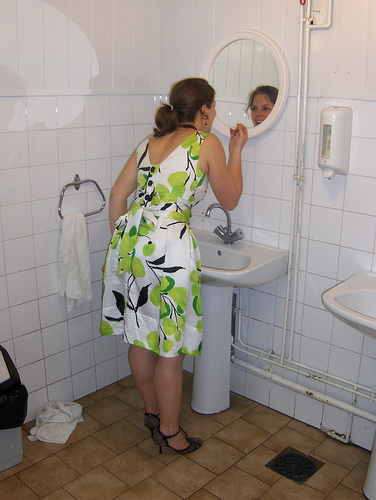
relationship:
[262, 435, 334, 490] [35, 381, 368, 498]
drain in floor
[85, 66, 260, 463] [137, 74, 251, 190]
lady fixing make up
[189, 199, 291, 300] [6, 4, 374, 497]
sink of bathroom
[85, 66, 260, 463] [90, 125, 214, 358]
lady has party dress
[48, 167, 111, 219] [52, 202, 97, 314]
holder of towel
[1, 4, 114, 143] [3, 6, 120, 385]
spot on wall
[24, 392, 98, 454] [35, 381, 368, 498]
towel on floor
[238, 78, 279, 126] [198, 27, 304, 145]
reflection in mirror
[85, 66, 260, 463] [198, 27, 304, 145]
woman looking in mirror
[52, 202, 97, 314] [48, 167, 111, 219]
towel hanging from rack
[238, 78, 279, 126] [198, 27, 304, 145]
face reflected in mirror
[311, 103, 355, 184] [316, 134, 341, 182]
dispenser of soap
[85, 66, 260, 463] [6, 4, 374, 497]
woman in a public restroom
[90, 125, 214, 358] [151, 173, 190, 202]
dress with green leaves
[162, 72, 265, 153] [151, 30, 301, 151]
lipstick being checked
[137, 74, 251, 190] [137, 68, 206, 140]
woman wearing ponytail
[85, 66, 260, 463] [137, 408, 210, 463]
woman wearing black heels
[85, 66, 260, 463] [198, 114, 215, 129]
woman wearing earrings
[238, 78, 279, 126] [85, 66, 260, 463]
reflection of woman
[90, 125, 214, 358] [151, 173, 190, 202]
dress with design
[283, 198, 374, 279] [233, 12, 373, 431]
shadow on wall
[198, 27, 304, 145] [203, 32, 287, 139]
mirror has white frame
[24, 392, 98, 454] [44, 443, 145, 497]
towel on ground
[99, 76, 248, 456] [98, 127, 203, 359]
lady wearing dress